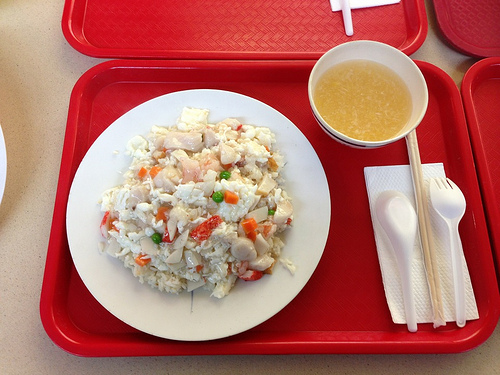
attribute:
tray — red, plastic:
[38, 59, 500, 358]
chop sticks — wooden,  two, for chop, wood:
[404, 128, 447, 327]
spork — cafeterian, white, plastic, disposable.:
[429, 175, 469, 326]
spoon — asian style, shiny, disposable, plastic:
[377, 190, 420, 333]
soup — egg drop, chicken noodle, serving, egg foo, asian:
[338, 77, 396, 121]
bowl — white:
[306, 37, 431, 151]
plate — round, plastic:
[64, 88, 333, 343]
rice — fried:
[136, 141, 162, 166]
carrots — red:
[242, 217, 273, 241]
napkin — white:
[363, 162, 479, 326]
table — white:
[2, 2, 61, 121]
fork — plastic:
[429, 175, 468, 330]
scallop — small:
[231, 238, 257, 262]